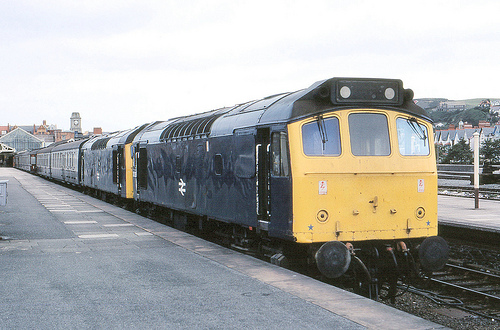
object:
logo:
[173, 177, 188, 197]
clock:
[69, 119, 85, 126]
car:
[33, 142, 61, 184]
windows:
[298, 115, 340, 159]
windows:
[66, 152, 77, 171]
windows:
[33, 153, 40, 168]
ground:
[418, 161, 500, 231]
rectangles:
[131, 231, 159, 240]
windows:
[347, 111, 390, 157]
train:
[8, 75, 450, 302]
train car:
[127, 75, 449, 304]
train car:
[76, 123, 163, 205]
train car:
[47, 136, 94, 188]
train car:
[10, 148, 39, 176]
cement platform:
[0, 166, 457, 329]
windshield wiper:
[313, 112, 328, 152]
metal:
[1, 134, 22, 152]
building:
[0, 126, 56, 160]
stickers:
[316, 179, 329, 196]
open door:
[253, 129, 275, 232]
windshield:
[299, 111, 432, 157]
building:
[27, 120, 74, 146]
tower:
[66, 110, 84, 133]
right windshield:
[390, 116, 443, 159]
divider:
[120, 140, 139, 200]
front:
[279, 74, 439, 246]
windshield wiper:
[403, 115, 429, 149]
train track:
[370, 260, 499, 329]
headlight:
[336, 86, 350, 100]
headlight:
[383, 88, 395, 99]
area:
[254, 125, 275, 232]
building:
[67, 108, 84, 144]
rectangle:
[78, 233, 121, 241]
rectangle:
[61, 221, 119, 235]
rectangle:
[50, 212, 96, 221]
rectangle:
[43, 207, 78, 213]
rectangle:
[35, 200, 71, 206]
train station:
[0, 32, 499, 328]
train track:
[431, 169, 499, 201]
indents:
[313, 208, 427, 222]